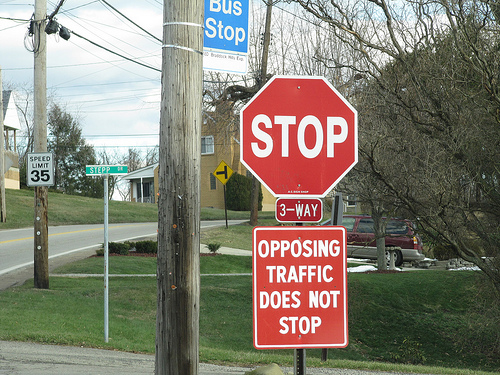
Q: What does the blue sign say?
A: Bus stop.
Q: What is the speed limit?
A: 35 mph.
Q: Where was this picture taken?
A: On a street.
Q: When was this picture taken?
A: Daytime.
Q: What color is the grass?
A: Green.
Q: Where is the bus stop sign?
A: On the pole.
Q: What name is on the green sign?
A: Stepp.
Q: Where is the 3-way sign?
A: Below the stop sign.